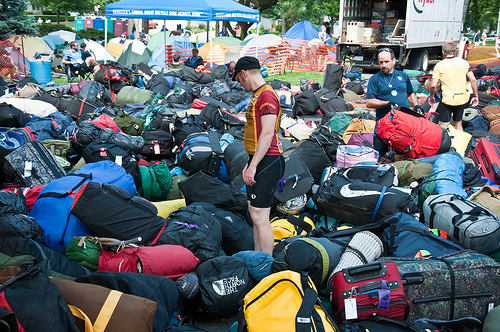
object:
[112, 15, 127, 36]
potties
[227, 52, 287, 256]
man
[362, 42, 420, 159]
man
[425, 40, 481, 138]
man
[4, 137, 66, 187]
duffel bags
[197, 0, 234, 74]
tent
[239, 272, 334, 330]
bag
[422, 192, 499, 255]
bag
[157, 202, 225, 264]
bag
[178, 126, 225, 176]
bag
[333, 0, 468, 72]
truck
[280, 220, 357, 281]
house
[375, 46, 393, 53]
sunglasses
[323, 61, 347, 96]
bag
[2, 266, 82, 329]
bag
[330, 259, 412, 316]
bag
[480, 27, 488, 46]
person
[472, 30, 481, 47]
person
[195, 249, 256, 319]
bags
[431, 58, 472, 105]
yellow shirt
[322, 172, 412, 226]
bag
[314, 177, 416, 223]
snow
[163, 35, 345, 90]
fence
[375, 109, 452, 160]
bag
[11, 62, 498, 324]
ground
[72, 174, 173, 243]
luggage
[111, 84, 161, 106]
luggage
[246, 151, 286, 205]
shorts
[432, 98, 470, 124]
shorts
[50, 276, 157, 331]
bag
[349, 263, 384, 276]
handle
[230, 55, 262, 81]
hat